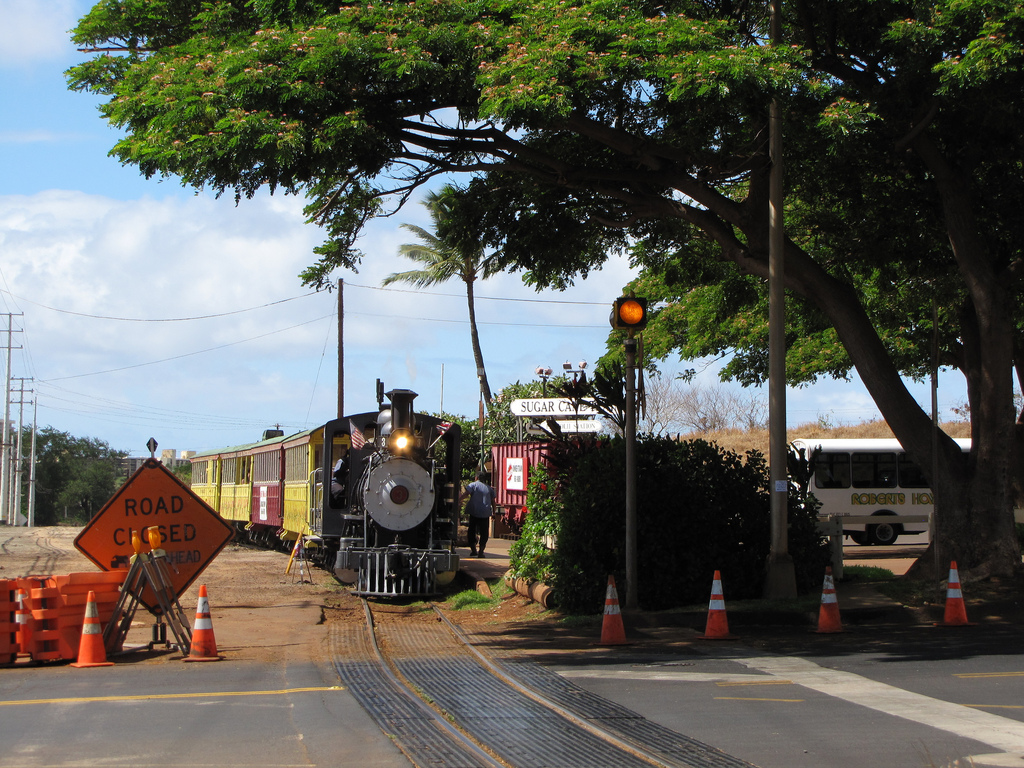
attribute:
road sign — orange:
[76, 461, 234, 616]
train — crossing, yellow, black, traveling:
[154, 390, 465, 604]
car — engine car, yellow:
[287, 385, 462, 613]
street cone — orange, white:
[184, 586, 225, 662]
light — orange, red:
[614, 300, 649, 329]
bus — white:
[787, 435, 939, 546]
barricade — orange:
[0, 566, 129, 666]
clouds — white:
[0, 193, 644, 451]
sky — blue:
[1, 1, 648, 462]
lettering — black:
[111, 496, 201, 566]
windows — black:
[807, 447, 932, 486]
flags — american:
[348, 415, 458, 456]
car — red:
[251, 443, 284, 533]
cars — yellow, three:
[190, 428, 318, 544]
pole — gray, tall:
[757, 0, 803, 608]